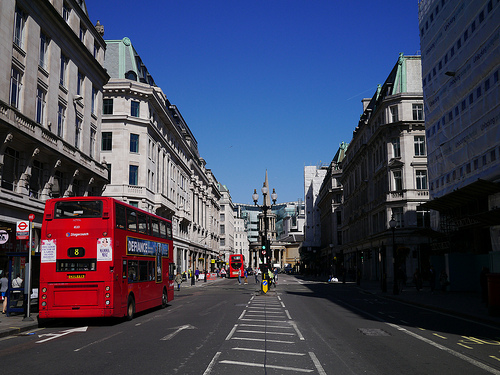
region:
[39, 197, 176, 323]
red double-decker bus close by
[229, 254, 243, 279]
red double-decker bus in the distance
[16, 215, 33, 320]
red bus stop sign on a pole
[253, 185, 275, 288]
street lamp in the middle of the road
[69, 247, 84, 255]
yellow number 8 on the back of the bus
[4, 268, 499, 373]
long road lined with buildings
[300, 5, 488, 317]
buildings on the right side of the road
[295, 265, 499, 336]
shade on the right side of the road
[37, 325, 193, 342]
arrows painted in white on the road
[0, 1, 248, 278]
buildings on the left side of the street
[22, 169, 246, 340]
a bus on the road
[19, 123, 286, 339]
a bus on the street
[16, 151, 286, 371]
a red bus on the road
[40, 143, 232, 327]
a red bus on the street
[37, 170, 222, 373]
a passenger bus on the road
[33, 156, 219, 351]
a passenger bus on the street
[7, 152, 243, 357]
a double decker bus on the road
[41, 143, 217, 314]
a double decker bus on the street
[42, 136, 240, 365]
a red double decker bus on the road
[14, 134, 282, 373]
a red double decker bus on the street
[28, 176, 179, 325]
a red double decker bus is on the street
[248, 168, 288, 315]
a street light is in the middle of the road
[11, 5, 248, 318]
several large buildings are in the area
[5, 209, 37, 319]
a street sign is on the sidewalk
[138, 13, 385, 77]
this portion of the sky is blue in color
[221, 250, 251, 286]
a second bus is further down the street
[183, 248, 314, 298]
several people are in this area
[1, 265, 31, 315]
two people walking on the sidewalk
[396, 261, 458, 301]
a group of people are walking on the sidwalk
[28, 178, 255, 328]
two double decker buses are on this side of the road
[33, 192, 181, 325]
double decker bus on street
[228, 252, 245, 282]
double decker bus behind first bus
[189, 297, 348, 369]
street area for vehicles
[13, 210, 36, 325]
pole with bus sign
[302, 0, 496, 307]
row of several buildings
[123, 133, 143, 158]
window in one of several buildings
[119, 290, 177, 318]
wheels to double decker bus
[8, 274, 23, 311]
a human on the sidewalk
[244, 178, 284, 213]
set of three lights on a pole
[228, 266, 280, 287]
people crossing the street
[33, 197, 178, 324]
double-decker bus on the street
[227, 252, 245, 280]
double-decker bus in the distance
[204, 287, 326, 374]
white line on the street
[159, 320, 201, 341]
arrow painted on the street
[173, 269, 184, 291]
person crossing the street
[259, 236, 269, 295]
traffic light on the street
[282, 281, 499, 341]
buildings shadow on the ground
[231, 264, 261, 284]
people walking on the street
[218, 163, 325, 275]
buildings in the background